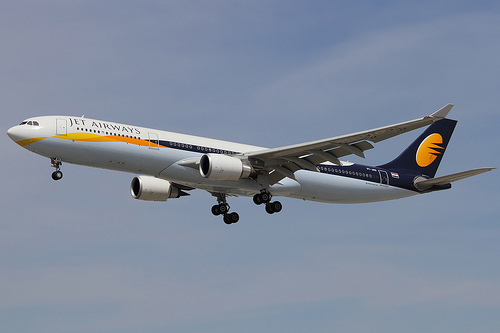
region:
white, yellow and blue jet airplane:
[48, 92, 497, 229]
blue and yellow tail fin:
[342, 109, 496, 218]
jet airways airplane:
[32, 93, 174, 205]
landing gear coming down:
[132, 138, 315, 253]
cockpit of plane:
[15, 110, 110, 216]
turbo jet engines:
[121, 151, 313, 232]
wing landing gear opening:
[270, 115, 440, 236]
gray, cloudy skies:
[23, 210, 379, 331]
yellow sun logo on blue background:
[403, 105, 475, 215]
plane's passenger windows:
[164, 118, 261, 170]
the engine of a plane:
[198, 147, 248, 182]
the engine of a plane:
[124, 172, 174, 205]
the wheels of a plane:
[211, 202, 227, 213]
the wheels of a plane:
[221, 211, 241, 226]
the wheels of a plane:
[253, 188, 268, 204]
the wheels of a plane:
[261, 200, 283, 216]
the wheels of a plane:
[51, 167, 64, 184]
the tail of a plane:
[386, 107, 494, 222]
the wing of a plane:
[246, 98, 456, 171]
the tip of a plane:
[6, 126, 21, 140]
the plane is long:
[21, 73, 470, 250]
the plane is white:
[16, 65, 496, 263]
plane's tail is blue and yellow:
[333, 45, 458, 248]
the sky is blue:
[130, 34, 378, 163]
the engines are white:
[11, 102, 406, 319]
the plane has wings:
[23, 48, 465, 327]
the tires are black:
[47, 155, 330, 290]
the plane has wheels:
[42, 170, 354, 290]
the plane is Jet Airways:
[47, 95, 241, 186]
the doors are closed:
[10, 113, 187, 158]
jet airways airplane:
[0, 65, 411, 244]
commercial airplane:
[10, 47, 377, 267]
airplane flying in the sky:
[33, 39, 485, 274]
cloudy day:
[29, 16, 461, 317]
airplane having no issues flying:
[257, 88, 449, 284]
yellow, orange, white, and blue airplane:
[30, 91, 448, 308]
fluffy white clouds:
[3, 187, 465, 308]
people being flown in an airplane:
[12, 22, 457, 312]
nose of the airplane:
[8, 88, 176, 249]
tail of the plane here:
[292, 52, 473, 274]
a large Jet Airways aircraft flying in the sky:
[9, 77, 499, 229]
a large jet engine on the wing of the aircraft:
[195, 151, 258, 183]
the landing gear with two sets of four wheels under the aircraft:
[210, 185, 285, 229]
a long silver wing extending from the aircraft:
[258, 98, 457, 153]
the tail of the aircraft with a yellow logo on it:
[397, 103, 466, 191]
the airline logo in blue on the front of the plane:
[68, 113, 145, 143]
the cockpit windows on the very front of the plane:
[20, 119, 41, 127]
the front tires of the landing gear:
[45, 163, 70, 183]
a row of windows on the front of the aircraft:
[79, 123, 144, 151]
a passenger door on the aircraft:
[145, 129, 159, 154]